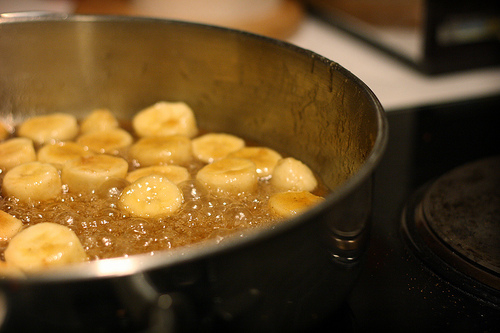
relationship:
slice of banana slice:
[193, 130, 247, 165] [5, 222, 86, 271]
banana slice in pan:
[5, 222, 86, 271] [1, 9, 393, 331]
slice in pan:
[1, 162, 60, 207] [3, 14, 390, 306]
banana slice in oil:
[119, 175, 183, 217] [61, 194, 264, 263]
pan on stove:
[8, 6, 433, 331] [3, 83, 495, 329]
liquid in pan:
[1, 121, 333, 263] [3, 14, 390, 306]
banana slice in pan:
[5, 222, 86, 271] [3, 14, 390, 306]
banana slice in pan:
[119, 175, 183, 217] [3, 14, 390, 306]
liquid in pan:
[0, 136, 328, 262] [3, 14, 390, 306]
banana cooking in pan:
[129, 97, 199, 140] [3, 14, 390, 306]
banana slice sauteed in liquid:
[119, 175, 183, 217] [0, 136, 328, 262]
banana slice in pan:
[206, 160, 256, 196] [250, 77, 370, 177]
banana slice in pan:
[241, 142, 282, 173] [250, 77, 370, 177]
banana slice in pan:
[66, 147, 116, 184] [250, 77, 370, 177]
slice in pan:
[192, 133, 245, 163] [250, 77, 370, 177]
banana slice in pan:
[6, 220, 93, 272] [250, 77, 370, 177]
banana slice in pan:
[5, 222, 86, 271] [0, 15, 387, 333]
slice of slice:
[192, 133, 245, 163] [192, 133, 245, 163]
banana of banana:
[133, 102, 196, 137] [27, 112, 228, 179]